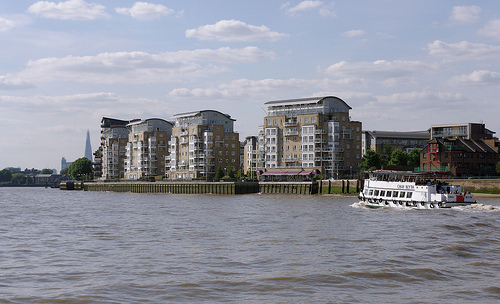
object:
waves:
[454, 202, 499, 214]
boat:
[357, 173, 476, 210]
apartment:
[257, 97, 361, 183]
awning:
[262, 169, 320, 175]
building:
[99, 109, 238, 180]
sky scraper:
[127, 117, 169, 178]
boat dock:
[58, 175, 365, 195]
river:
[0, 186, 499, 301]